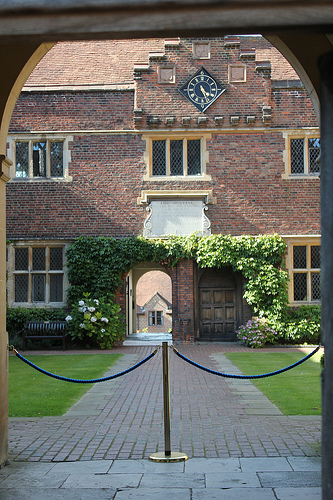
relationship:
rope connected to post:
[171, 343, 325, 380] [147, 340, 188, 462]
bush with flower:
[234, 315, 277, 347] [256, 331, 264, 337]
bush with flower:
[63, 290, 125, 349] [86, 306, 95, 314]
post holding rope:
[147, 340, 188, 462] [11, 345, 162, 384]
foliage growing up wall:
[65, 233, 290, 343] [8, 36, 322, 346]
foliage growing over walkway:
[65, 233, 290, 343] [123, 262, 174, 344]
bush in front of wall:
[234, 315, 277, 347] [8, 36, 322, 346]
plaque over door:
[148, 199, 206, 238] [197, 264, 239, 342]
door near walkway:
[197, 264, 239, 342] [123, 262, 174, 344]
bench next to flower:
[17, 319, 69, 347] [86, 306, 95, 314]